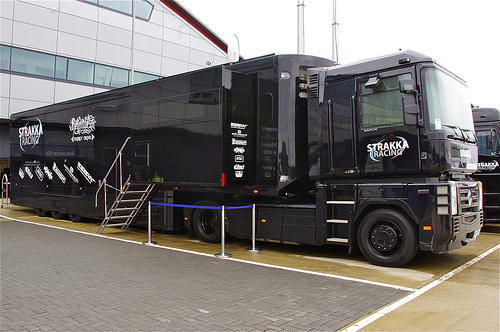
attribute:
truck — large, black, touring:
[464, 99, 484, 222]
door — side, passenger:
[351, 66, 421, 174]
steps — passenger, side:
[324, 191, 356, 249]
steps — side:
[96, 166, 150, 230]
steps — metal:
[101, 173, 152, 234]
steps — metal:
[324, 188, 354, 248]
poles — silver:
[142, 200, 262, 256]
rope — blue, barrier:
[150, 199, 253, 213]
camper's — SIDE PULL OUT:
[30, 45, 483, 267]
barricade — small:
[133, 188, 263, 264]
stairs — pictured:
[93, 172, 152, 231]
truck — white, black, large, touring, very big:
[6, 47, 484, 261]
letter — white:
[366, 138, 373, 157]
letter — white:
[401, 139, 409, 152]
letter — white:
[397, 138, 405, 154]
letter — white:
[382, 137, 392, 154]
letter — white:
[386, 139, 396, 151]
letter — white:
[399, 139, 413, 152]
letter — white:
[373, 149, 382, 159]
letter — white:
[394, 149, 404, 159]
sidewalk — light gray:
[2, 215, 412, 330]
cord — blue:
[149, 199, 221, 210]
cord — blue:
[222, 202, 252, 217]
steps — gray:
[92, 131, 158, 241]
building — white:
[0, 2, 244, 169]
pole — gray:
[293, 1, 312, 55]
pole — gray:
[327, 1, 342, 59]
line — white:
[332, 259, 483, 329]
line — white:
[2, 213, 413, 293]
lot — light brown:
[2, 200, 483, 329]